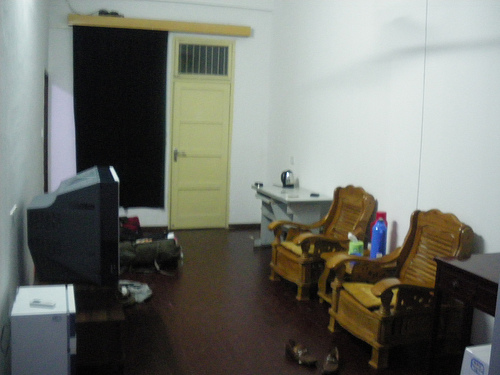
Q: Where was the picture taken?
A: In a living room.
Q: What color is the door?
A: Yellow.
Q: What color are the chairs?
A: Brown.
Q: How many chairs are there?
A: 2.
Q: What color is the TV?
A: Black.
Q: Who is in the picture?
A: No one.